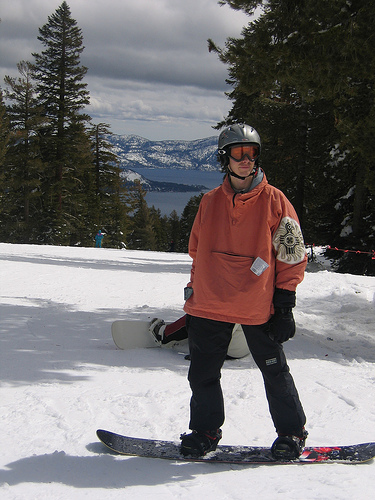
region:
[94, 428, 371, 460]
a black and red snowboard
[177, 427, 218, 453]
a snowboard boot and binder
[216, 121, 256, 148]
a snowboarder ski helmet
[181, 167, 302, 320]
an orange colored ski jacket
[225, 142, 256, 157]
amber colored ski goggles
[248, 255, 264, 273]
a ski lift ticket pass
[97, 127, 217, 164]
tall mountains in the distance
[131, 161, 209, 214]
a mountain lake in the distance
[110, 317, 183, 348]
a white snowboard in the snow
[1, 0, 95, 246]
tall pine trees bordering the ski trail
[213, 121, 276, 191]
Person wearing helmet and goggles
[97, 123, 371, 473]
Man standing on a snowboard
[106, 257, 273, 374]
Person on ground behind standing snowboarder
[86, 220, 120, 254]
Person in blue walking up hill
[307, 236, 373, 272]
Ski trail roped off with orange banner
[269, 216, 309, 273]
Eagle graphic on man's sleeve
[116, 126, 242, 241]
Lake and mountains behind snowboarder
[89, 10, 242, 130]
Grey and white clouds in sky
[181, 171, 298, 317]
Orange sweatshirt with kangaroo pocket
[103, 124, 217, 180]
Snow-covered mountains surrounding lake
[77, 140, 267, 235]
A blue lake in the background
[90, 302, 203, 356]
A white snowboard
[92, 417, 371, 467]
A black snowboard with some red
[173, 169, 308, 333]
An orange jacket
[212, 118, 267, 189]
A helmet with a chin strap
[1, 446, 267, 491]
Shadow of the snowboarder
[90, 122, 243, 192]
Mountains in the distance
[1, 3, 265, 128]
A cloudy sky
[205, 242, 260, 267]
A horizontal zipper on an orange jacket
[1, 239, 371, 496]
Snow covered ground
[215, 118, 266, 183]
the head of a man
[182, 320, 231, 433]
the leg of a man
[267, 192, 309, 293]
the arm of a man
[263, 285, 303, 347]
a black glove on the man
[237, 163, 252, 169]
the mouth of a man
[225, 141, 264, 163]
a pair of goggles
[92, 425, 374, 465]
a black snowboard under the man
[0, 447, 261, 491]
a shadow on the ground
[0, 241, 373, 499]
white snow on the ground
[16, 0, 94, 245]
a large green tree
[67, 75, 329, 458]
a man on a snowboard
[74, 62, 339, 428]
a man wearing a helmet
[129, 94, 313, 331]
a man wearing a silver helmet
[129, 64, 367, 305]
a snowboarder wearing a helmet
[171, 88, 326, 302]
a man wearing googles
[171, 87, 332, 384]
a man wearing a jacket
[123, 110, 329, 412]
a man wearing gloves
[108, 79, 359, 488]
a man wearing pants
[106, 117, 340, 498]
a man wearing black pants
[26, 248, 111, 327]
snow covering the ground